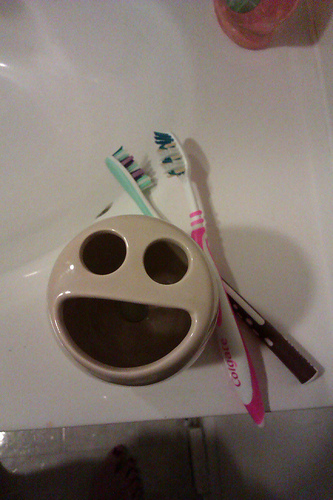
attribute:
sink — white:
[230, 61, 331, 227]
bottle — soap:
[207, 1, 303, 54]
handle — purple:
[184, 176, 265, 429]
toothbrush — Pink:
[150, 128, 273, 435]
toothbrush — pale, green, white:
[103, 145, 265, 326]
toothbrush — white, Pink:
[151, 120, 265, 427]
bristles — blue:
[150, 128, 187, 179]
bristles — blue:
[108, 143, 154, 193]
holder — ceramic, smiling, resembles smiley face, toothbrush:
[46, 213, 221, 387]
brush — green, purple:
[104, 144, 158, 210]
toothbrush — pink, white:
[100, 123, 278, 331]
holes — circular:
[72, 226, 195, 287]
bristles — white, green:
[112, 130, 186, 187]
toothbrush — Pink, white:
[166, 165, 284, 356]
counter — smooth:
[193, 364, 320, 457]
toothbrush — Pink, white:
[103, 145, 318, 383]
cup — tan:
[43, 209, 215, 392]